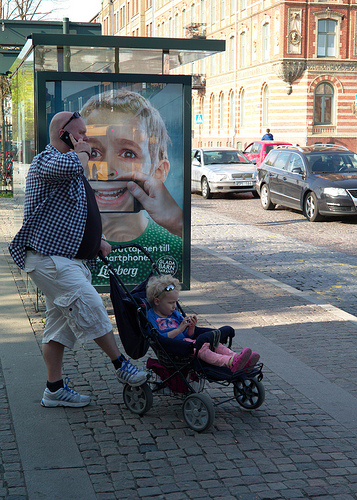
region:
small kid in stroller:
[118, 265, 268, 429]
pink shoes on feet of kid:
[229, 348, 260, 368]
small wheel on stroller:
[175, 391, 216, 430]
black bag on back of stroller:
[106, 280, 145, 357]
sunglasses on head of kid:
[159, 278, 174, 293]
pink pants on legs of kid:
[186, 332, 229, 358]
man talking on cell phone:
[29, 113, 102, 180]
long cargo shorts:
[34, 263, 106, 350]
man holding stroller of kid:
[18, 94, 174, 415]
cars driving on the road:
[187, 126, 291, 206]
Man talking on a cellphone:
[7, 109, 151, 408]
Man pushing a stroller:
[9, 110, 266, 432]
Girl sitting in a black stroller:
[98, 241, 266, 432]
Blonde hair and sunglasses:
[145, 273, 181, 307]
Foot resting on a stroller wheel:
[113, 355, 153, 395]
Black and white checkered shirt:
[7, 142, 85, 270]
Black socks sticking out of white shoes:
[40, 353, 151, 409]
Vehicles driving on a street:
[191, 139, 355, 223]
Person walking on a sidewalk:
[263, 126, 274, 149]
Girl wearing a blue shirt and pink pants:
[143, 273, 258, 370]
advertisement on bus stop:
[73, 76, 182, 289]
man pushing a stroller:
[30, 116, 306, 464]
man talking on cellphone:
[37, 118, 95, 169]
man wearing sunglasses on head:
[50, 102, 97, 132]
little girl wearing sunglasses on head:
[147, 273, 186, 314]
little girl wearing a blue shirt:
[146, 308, 200, 339]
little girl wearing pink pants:
[190, 338, 254, 370]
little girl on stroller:
[140, 267, 275, 436]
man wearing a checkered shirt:
[1, 145, 100, 266]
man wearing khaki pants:
[19, 251, 115, 362]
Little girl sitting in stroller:
[128, 259, 270, 426]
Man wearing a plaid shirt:
[12, 103, 158, 411]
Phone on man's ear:
[51, 131, 86, 157]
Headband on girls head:
[159, 275, 181, 299]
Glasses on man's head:
[51, 107, 86, 133]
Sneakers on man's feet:
[26, 353, 149, 421]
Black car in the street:
[257, 139, 356, 230]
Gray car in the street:
[182, 138, 256, 204]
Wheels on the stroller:
[108, 361, 271, 443]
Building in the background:
[92, 0, 356, 172]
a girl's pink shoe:
[227, 345, 255, 369]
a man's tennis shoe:
[37, 386, 93, 408]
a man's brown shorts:
[19, 249, 116, 347]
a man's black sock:
[46, 379, 65, 392]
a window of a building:
[317, 19, 338, 60]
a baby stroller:
[98, 239, 269, 429]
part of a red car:
[239, 141, 290, 170]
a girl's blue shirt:
[144, 307, 189, 341]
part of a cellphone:
[59, 132, 73, 147]